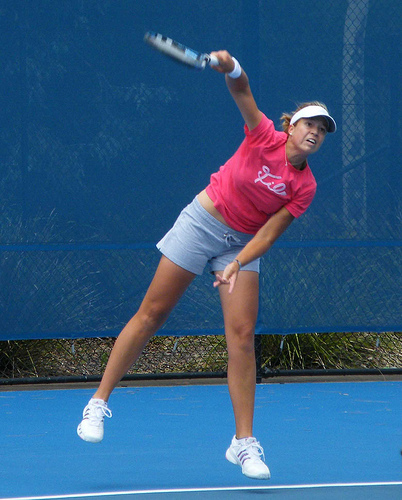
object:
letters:
[254, 165, 287, 197]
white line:
[0, 478, 400, 497]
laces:
[244, 441, 266, 462]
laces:
[83, 399, 113, 419]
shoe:
[76, 397, 113, 443]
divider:
[3, 2, 400, 340]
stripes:
[237, 450, 250, 465]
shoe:
[226, 435, 271, 480]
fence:
[0, 331, 402, 384]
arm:
[235, 206, 295, 266]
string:
[223, 230, 238, 248]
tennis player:
[75, 48, 337, 479]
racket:
[144, 30, 220, 70]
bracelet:
[234, 259, 242, 269]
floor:
[283, 379, 402, 482]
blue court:
[1, 380, 400, 498]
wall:
[230, 85, 279, 120]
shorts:
[156, 195, 260, 275]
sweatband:
[228, 57, 242, 80]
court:
[0, 46, 400, 500]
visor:
[290, 105, 337, 133]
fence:
[0, 3, 400, 384]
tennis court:
[0, 372, 398, 494]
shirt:
[206, 113, 317, 235]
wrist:
[234, 255, 243, 268]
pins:
[243, 442, 262, 453]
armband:
[227, 57, 241, 79]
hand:
[210, 50, 234, 73]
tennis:
[13, 19, 355, 480]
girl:
[77, 31, 337, 482]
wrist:
[228, 57, 237, 74]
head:
[288, 101, 329, 155]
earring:
[290, 132, 293, 135]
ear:
[288, 124, 295, 136]